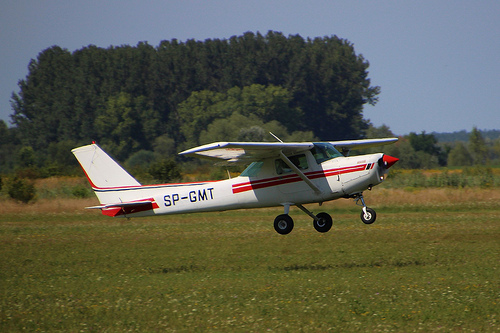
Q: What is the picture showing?
A: It is showing a forest.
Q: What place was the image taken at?
A: It was taken at the forest.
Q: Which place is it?
A: It is a forest.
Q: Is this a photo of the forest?
A: Yes, it is showing the forest.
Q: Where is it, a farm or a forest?
A: It is a forest.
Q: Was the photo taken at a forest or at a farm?
A: It was taken at a forest.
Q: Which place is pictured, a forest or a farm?
A: It is a forest.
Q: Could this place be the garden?
A: No, it is the forest.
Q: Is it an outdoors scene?
A: Yes, it is outdoors.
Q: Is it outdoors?
A: Yes, it is outdoors.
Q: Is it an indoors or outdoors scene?
A: It is outdoors.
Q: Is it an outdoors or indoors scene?
A: It is outdoors.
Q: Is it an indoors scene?
A: No, it is outdoors.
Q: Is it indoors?
A: No, it is outdoors.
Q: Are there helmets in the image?
A: No, there are no helmets.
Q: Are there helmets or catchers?
A: No, there are no helmets or catchers.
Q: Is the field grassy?
A: Yes, the field is grassy.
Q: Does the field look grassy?
A: Yes, the field is grassy.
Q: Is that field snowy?
A: No, the field is grassy.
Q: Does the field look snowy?
A: No, the field is grassy.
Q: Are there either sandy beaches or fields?
A: No, there is a field but it is grassy.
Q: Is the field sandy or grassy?
A: The field is grassy.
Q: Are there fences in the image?
A: No, there are no fences.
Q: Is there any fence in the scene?
A: No, there are no fences.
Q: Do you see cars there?
A: No, there are no cars.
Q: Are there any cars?
A: No, there are no cars.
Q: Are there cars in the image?
A: No, there are no cars.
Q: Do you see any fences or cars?
A: No, there are no cars or fences.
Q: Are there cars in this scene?
A: No, there are no cars.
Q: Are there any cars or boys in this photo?
A: No, there are no cars or boys.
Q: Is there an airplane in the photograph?
A: Yes, there is an airplane.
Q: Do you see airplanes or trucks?
A: Yes, there is an airplane.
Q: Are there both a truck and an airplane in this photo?
A: No, there is an airplane but no trucks.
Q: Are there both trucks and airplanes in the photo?
A: No, there is an airplane but no trucks.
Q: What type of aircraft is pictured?
A: The aircraft is an airplane.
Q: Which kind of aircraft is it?
A: The aircraft is an airplane.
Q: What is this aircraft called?
A: That is an airplane.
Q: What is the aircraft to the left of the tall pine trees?
A: The aircraft is an airplane.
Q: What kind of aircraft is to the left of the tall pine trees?
A: The aircraft is an airplane.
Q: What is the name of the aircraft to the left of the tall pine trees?
A: The aircraft is an airplane.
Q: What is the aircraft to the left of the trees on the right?
A: The aircraft is an airplane.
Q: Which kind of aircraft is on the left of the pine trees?
A: The aircraft is an airplane.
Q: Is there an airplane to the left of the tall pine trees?
A: Yes, there is an airplane to the left of the pine trees.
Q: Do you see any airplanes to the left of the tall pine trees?
A: Yes, there is an airplane to the left of the pine trees.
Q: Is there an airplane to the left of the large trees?
A: Yes, there is an airplane to the left of the pine trees.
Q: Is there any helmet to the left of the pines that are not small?
A: No, there is an airplane to the left of the pine trees.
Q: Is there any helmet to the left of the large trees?
A: No, there is an airplane to the left of the pine trees.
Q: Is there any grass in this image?
A: Yes, there is grass.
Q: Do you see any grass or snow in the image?
A: Yes, there is grass.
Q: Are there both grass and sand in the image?
A: No, there is grass but no sand.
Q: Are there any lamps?
A: No, there are no lamps.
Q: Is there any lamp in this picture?
A: No, there are no lamps.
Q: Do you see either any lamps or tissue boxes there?
A: No, there are no lamps or tissue boxes.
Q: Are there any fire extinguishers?
A: No, there are no fire extinguishers.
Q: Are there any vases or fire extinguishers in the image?
A: No, there are no fire extinguishers or vases.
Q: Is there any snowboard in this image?
A: No, there are no snowboards.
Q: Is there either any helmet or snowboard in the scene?
A: No, there are no snowboards or helmets.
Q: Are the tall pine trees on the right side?
A: Yes, the pine trees are on the right of the image.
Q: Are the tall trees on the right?
A: Yes, the pine trees are on the right of the image.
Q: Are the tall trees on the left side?
A: No, the pines are on the right of the image.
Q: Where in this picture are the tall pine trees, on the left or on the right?
A: The pine trees are on the right of the image.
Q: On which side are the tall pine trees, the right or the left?
A: The pine trees are on the right of the image.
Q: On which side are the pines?
A: The pines are on the right of the image.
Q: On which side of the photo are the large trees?
A: The pines are on the right of the image.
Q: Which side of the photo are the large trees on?
A: The pines are on the right of the image.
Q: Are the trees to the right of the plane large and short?
A: No, the pines are large but tall.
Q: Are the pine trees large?
A: Yes, the pine trees are large.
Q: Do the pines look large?
A: Yes, the pines are large.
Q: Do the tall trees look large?
A: Yes, the pines are large.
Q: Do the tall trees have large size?
A: Yes, the pines are large.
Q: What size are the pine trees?
A: The pine trees are large.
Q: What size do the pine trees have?
A: The pine trees have large size.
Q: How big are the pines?
A: The pines are large.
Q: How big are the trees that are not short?
A: The pines are large.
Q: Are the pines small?
A: No, the pines are large.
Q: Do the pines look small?
A: No, the pines are large.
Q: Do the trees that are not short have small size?
A: No, the pines are large.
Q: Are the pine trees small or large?
A: The pine trees are large.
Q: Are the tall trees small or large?
A: The pine trees are large.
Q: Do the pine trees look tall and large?
A: Yes, the pine trees are tall and large.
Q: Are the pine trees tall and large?
A: Yes, the pine trees are tall and large.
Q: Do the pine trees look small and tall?
A: No, the pine trees are tall but large.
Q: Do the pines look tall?
A: Yes, the pines are tall.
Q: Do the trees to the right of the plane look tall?
A: Yes, the pines are tall.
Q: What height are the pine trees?
A: The pine trees are tall.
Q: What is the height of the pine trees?
A: The pine trees are tall.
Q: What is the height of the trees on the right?
A: The pine trees are tall.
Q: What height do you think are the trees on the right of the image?
A: The pine trees are tall.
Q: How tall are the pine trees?
A: The pine trees are tall.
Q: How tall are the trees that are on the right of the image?
A: The pine trees are tall.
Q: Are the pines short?
A: No, the pines are tall.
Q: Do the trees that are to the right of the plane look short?
A: No, the pines are tall.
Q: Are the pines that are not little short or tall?
A: The pines are tall.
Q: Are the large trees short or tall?
A: The pines are tall.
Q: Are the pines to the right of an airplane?
A: Yes, the pines are to the right of an airplane.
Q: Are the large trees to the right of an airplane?
A: Yes, the pines are to the right of an airplane.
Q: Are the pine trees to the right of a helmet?
A: No, the pine trees are to the right of an airplane.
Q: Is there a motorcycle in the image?
A: No, there are no motorcycles.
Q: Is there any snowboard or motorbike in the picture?
A: No, there are no motorcycles or snowboards.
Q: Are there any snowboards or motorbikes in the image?
A: No, there are no motorbikes or snowboards.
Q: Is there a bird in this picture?
A: No, there are no birds.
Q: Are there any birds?
A: No, there are no birds.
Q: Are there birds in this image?
A: No, there are no birds.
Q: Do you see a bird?
A: No, there are no birds.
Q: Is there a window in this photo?
A: Yes, there is a window.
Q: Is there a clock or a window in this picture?
A: Yes, there is a window.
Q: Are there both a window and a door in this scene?
A: No, there is a window but no doors.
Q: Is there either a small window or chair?
A: Yes, there is a small window.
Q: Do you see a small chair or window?
A: Yes, there is a small window.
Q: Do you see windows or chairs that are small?
A: Yes, the window is small.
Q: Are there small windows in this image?
A: Yes, there is a small window.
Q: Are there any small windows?
A: Yes, there is a small window.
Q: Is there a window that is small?
A: Yes, there is a window that is small.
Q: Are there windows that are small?
A: Yes, there is a window that is small.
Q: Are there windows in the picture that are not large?
A: Yes, there is a small window.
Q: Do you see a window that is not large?
A: Yes, there is a small window.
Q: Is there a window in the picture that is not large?
A: Yes, there is a small window.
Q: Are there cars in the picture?
A: No, there are no cars.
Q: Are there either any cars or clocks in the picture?
A: No, there are no cars or clocks.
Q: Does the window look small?
A: Yes, the window is small.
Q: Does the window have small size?
A: Yes, the window is small.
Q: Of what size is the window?
A: The window is small.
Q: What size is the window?
A: The window is small.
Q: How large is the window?
A: The window is small.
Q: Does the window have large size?
A: No, the window is small.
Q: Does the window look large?
A: No, the window is small.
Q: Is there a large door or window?
A: No, there is a window but it is small.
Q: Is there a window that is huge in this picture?
A: No, there is a window but it is small.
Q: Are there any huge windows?
A: No, there is a window but it is small.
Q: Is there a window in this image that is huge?
A: No, there is a window but it is small.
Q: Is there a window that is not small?
A: No, there is a window but it is small.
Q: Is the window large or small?
A: The window is small.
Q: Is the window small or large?
A: The window is small.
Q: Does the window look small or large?
A: The window is small.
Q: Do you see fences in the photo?
A: No, there are no fences.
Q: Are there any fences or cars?
A: No, there are no fences or cars.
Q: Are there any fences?
A: No, there are no fences.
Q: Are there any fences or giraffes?
A: No, there are no fences or giraffes.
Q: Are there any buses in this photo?
A: No, there are no buses.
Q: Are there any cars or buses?
A: No, there are no buses or cars.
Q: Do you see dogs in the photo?
A: No, there are no dogs.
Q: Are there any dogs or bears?
A: No, there are no dogs or bears.